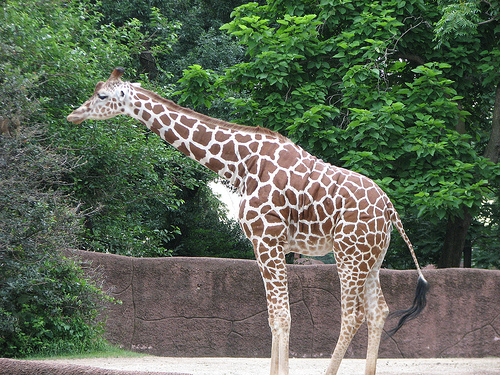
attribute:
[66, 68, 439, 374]
giraffe — brown, white, spotted, tall, short, skinny, standing, Tail, Ear, Eye 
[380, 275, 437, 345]
hair — black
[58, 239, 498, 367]
wall — stone, dark brown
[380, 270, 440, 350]
hair — long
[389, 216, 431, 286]
tail — thin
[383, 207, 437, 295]
tail — spotted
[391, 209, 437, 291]
tail — long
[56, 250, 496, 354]
wall — stone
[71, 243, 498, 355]
wall — stone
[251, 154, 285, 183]
spot — upside down, heart-shaped, brown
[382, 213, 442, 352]
tail — still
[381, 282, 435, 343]
hair — black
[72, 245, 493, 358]
concrete wall — low, brown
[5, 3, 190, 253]
tree — green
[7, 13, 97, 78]
foilage — large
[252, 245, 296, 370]
leg — long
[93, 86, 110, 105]
eye — large, closed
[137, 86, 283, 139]
mane — long, stiff, brown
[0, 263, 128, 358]
bush — short, dark green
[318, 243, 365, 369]
leg — long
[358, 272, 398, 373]
leg — long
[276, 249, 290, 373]
leg — long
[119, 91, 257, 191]
neck — long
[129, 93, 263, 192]
neck — long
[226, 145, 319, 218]
spots — brown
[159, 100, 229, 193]
neck — zebras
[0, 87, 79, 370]
bush — green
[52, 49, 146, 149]
head — zebras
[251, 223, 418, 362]
legs — four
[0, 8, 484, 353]
scene — zoo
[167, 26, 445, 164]
trees — background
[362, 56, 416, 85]
sky — white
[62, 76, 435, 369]
animal — spot 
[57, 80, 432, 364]
giraffe — Head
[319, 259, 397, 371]
legs — back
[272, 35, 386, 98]
leaves — green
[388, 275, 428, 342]
hair — black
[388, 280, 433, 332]
hair — black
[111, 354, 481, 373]
ground — light brown dirt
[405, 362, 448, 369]
zebra — Tail 